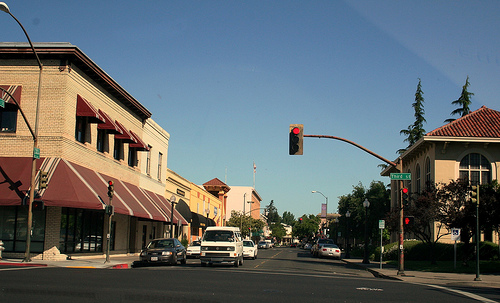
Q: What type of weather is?
A: It is clear.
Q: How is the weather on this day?
A: It is clear.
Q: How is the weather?
A: It is clear.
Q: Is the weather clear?
A: Yes, it is clear.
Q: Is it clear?
A: Yes, it is clear.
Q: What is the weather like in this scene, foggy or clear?
A: It is clear.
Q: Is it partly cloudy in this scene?
A: No, it is clear.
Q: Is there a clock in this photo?
A: No, there are no clocks.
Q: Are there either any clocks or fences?
A: No, there are no clocks or fences.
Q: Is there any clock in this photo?
A: No, there are no clocks.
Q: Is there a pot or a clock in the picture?
A: No, there are no clocks or pots.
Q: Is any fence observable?
A: No, there are no fences.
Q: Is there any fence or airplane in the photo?
A: No, there are no fences or airplanes.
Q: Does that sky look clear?
A: Yes, the sky is clear.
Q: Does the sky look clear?
A: Yes, the sky is clear.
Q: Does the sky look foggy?
A: No, the sky is clear.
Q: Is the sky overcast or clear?
A: The sky is clear.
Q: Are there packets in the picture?
A: No, there are no packets.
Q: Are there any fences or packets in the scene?
A: No, there are no packets or fences.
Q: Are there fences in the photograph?
A: No, there are no fences.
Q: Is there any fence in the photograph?
A: No, there are no fences.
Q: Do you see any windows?
A: Yes, there is a window.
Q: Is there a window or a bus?
A: Yes, there is a window.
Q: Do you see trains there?
A: No, there are no trains.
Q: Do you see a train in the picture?
A: No, there are no trains.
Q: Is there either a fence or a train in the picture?
A: No, there are no trains or fences.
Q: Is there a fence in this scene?
A: No, there are no fences.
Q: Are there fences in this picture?
A: No, there are no fences.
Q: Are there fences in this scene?
A: No, there are no fences.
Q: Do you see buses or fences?
A: No, there are no fences or buses.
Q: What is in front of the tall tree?
A: The building is in front of the tree.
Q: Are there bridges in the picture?
A: Yes, there is a bridge.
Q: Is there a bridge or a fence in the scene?
A: Yes, there is a bridge.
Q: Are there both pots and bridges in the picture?
A: No, there is a bridge but no pots.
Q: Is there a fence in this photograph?
A: No, there are no fences.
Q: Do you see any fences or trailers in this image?
A: No, there are no fences or trailers.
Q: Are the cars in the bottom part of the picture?
A: Yes, the cars are in the bottom of the image.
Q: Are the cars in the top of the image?
A: No, the cars are in the bottom of the image.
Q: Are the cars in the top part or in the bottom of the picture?
A: The cars are in the bottom of the image.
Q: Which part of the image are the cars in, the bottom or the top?
A: The cars are in the bottom of the image.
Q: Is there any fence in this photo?
A: No, there are no fences.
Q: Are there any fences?
A: No, there are no fences.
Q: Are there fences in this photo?
A: No, there are no fences.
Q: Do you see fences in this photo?
A: No, there are no fences.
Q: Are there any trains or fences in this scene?
A: No, there are no fences or trains.